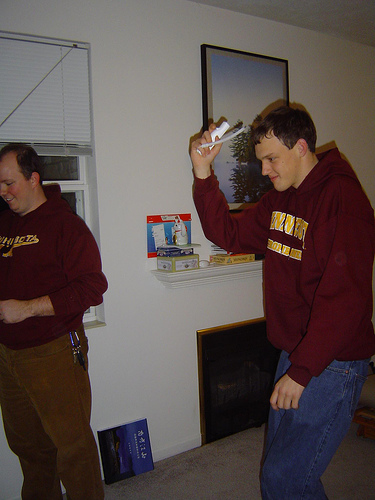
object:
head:
[247, 96, 319, 192]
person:
[186, 94, 373, 500]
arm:
[191, 166, 271, 253]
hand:
[187, 123, 224, 178]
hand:
[268, 368, 304, 413]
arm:
[289, 182, 373, 373]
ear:
[294, 137, 308, 158]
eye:
[265, 155, 277, 164]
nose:
[259, 160, 275, 179]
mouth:
[268, 172, 277, 183]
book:
[95, 413, 154, 484]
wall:
[0, 2, 375, 500]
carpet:
[9, 415, 373, 499]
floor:
[24, 418, 374, 499]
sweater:
[187, 145, 374, 393]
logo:
[261, 210, 314, 272]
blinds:
[1, 35, 96, 163]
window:
[1, 28, 95, 320]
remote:
[197, 116, 242, 162]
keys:
[77, 351, 93, 382]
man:
[0, 140, 108, 496]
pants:
[1, 325, 104, 500]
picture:
[198, 40, 297, 219]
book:
[210, 251, 258, 265]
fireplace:
[196, 312, 297, 446]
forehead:
[248, 131, 272, 159]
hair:
[248, 100, 319, 157]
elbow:
[217, 232, 239, 255]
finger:
[209, 120, 219, 134]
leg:
[259, 361, 371, 500]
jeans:
[256, 344, 367, 500]